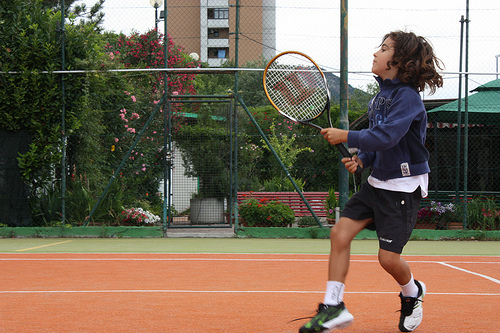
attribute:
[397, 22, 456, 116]
hair — brown , curly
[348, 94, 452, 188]
sweater — blue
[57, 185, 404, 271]
fence — green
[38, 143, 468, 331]
court — orange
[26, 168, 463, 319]
court — orange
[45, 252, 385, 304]
line — White 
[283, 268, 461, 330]
shoe — White , green 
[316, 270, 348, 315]
sock — long , white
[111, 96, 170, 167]
flower — pink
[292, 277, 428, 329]
shoes — white, black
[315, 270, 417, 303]
socks — white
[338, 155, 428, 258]
shorts — black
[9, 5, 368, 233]
bushes — green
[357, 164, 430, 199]
shirt — white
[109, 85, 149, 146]
flower — pink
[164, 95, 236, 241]
gate — green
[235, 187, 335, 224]
bench — pink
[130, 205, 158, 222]
flower — white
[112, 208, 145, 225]
flower — red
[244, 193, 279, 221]
flowers — red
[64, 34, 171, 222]
tree — green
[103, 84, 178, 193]
flowers — pink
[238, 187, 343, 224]
bench — red